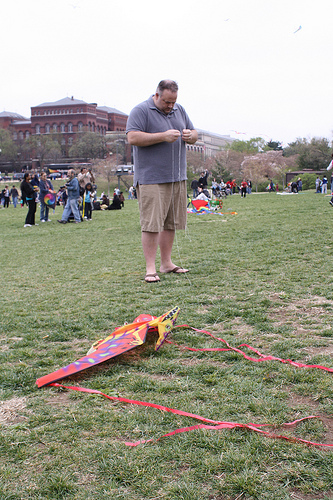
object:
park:
[1, 169, 330, 497]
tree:
[239, 141, 268, 186]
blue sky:
[234, 105, 294, 130]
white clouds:
[83, 18, 161, 50]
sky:
[2, 0, 331, 121]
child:
[83, 186, 93, 220]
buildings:
[0, 99, 265, 180]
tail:
[102, 384, 309, 466]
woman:
[39, 177, 49, 219]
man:
[126, 78, 197, 281]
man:
[193, 169, 213, 192]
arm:
[127, 105, 163, 146]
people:
[22, 177, 33, 225]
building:
[0, 93, 134, 175]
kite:
[37, 306, 182, 388]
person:
[189, 182, 212, 212]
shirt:
[126, 97, 192, 189]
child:
[31, 170, 40, 195]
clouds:
[210, 20, 237, 53]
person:
[237, 178, 246, 198]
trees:
[110, 132, 122, 166]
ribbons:
[160, 136, 196, 194]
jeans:
[39, 201, 46, 213]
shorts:
[141, 183, 187, 234]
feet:
[144, 269, 160, 282]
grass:
[0, 177, 331, 494]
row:
[4, 131, 132, 157]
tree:
[2, 128, 18, 164]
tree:
[19, 129, 44, 167]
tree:
[68, 132, 88, 157]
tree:
[107, 135, 127, 155]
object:
[203, 167, 211, 179]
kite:
[298, 18, 306, 36]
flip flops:
[145, 270, 158, 280]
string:
[169, 131, 219, 328]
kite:
[41, 187, 59, 209]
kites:
[187, 199, 207, 215]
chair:
[202, 188, 213, 201]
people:
[88, 189, 124, 210]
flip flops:
[164, 265, 186, 269]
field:
[0, 174, 333, 497]